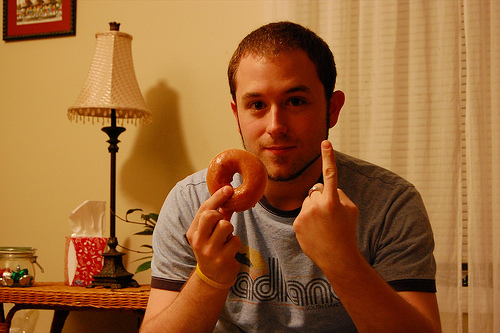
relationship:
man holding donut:
[139, 22, 443, 332] [205, 150, 267, 212]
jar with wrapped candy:
[1, 244, 45, 287] [2, 266, 33, 287]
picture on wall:
[2, 1, 76, 43] [1, 1, 264, 330]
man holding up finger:
[139, 22, 443, 332] [320, 140, 336, 193]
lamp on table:
[69, 20, 140, 290] [1, 282, 152, 329]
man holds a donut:
[139, 22, 443, 332] [205, 150, 267, 212]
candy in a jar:
[2, 266, 33, 287] [1, 244, 45, 287]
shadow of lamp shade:
[119, 82, 196, 212] [69, 31, 148, 121]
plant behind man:
[114, 205, 159, 272] [139, 22, 443, 332]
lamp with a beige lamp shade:
[69, 20, 140, 290] [69, 31, 148, 121]